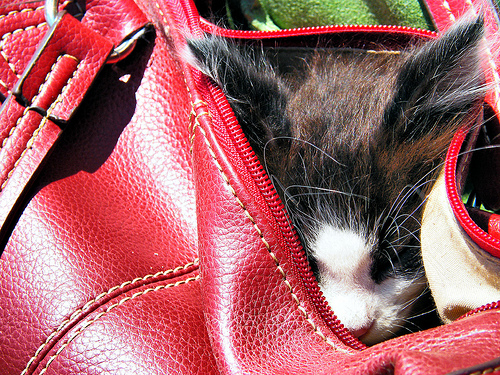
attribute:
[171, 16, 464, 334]
cat — hairy, spotted, furry, white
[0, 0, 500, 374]
bag — red, zippered, stitched, leather, seamed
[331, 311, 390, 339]
nose — pink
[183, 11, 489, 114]
ears — black